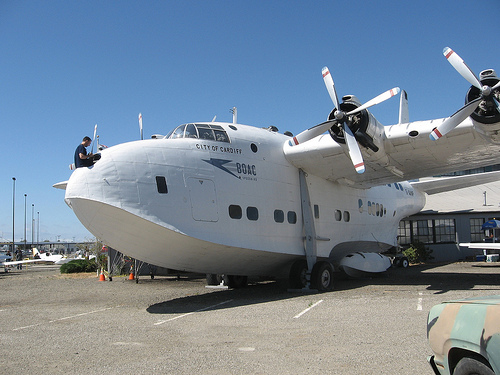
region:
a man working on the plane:
[63, 125, 102, 171]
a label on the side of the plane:
[197, 154, 267, 193]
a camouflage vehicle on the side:
[424, 288, 496, 371]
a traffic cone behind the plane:
[93, 259, 106, 280]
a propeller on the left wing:
[279, 62, 414, 174]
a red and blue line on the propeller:
[282, 129, 299, 148]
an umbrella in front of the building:
[483, 212, 498, 233]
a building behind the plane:
[394, 172, 499, 257]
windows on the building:
[393, 217, 460, 247]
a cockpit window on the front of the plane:
[163, 119, 235, 149]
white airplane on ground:
[69, 51, 486, 323]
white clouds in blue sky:
[17, 18, 59, 80]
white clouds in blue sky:
[33, 51, 88, 89]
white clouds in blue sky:
[80, 18, 127, 40]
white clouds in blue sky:
[90, 51, 135, 92]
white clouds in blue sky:
[193, 17, 227, 72]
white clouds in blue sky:
[223, 38, 264, 95]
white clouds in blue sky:
[339, 36, 373, 73]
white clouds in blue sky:
[387, 11, 414, 48]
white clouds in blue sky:
[29, 170, 46, 195]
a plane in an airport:
[45, 41, 497, 309]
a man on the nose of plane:
[57, 129, 152, 237]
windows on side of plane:
[151, 169, 398, 240]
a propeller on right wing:
[413, 37, 496, 143]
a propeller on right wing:
[285, 61, 405, 176]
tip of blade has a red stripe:
[312, 58, 334, 83]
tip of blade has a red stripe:
[383, 80, 403, 100]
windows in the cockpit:
[156, 111, 236, 157]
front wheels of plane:
[207, 255, 342, 295]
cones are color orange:
[91, 259, 138, 289]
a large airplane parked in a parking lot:
[26, 16, 496, 297]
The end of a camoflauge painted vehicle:
[423, 301, 499, 373]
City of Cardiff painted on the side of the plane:
[194, 143, 243, 155]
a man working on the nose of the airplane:
[73, 129, 100, 171]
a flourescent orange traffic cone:
[95, 268, 107, 283]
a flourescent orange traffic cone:
[123, 265, 138, 282]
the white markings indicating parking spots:
[23, 280, 441, 345]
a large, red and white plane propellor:
[283, 59, 407, 175]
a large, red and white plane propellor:
[424, 33, 499, 153]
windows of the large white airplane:
[226, 198, 300, 230]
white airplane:
[64, 93, 499, 285]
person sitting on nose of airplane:
[64, 137, 101, 167]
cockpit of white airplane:
[159, 122, 234, 145]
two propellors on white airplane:
[265, 23, 498, 168]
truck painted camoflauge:
[422, 287, 499, 367]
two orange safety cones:
[92, 263, 146, 280]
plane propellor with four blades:
[286, 81, 397, 173]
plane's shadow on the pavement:
[145, 268, 486, 318]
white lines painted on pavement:
[28, 276, 431, 332]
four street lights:
[9, 171, 43, 259]